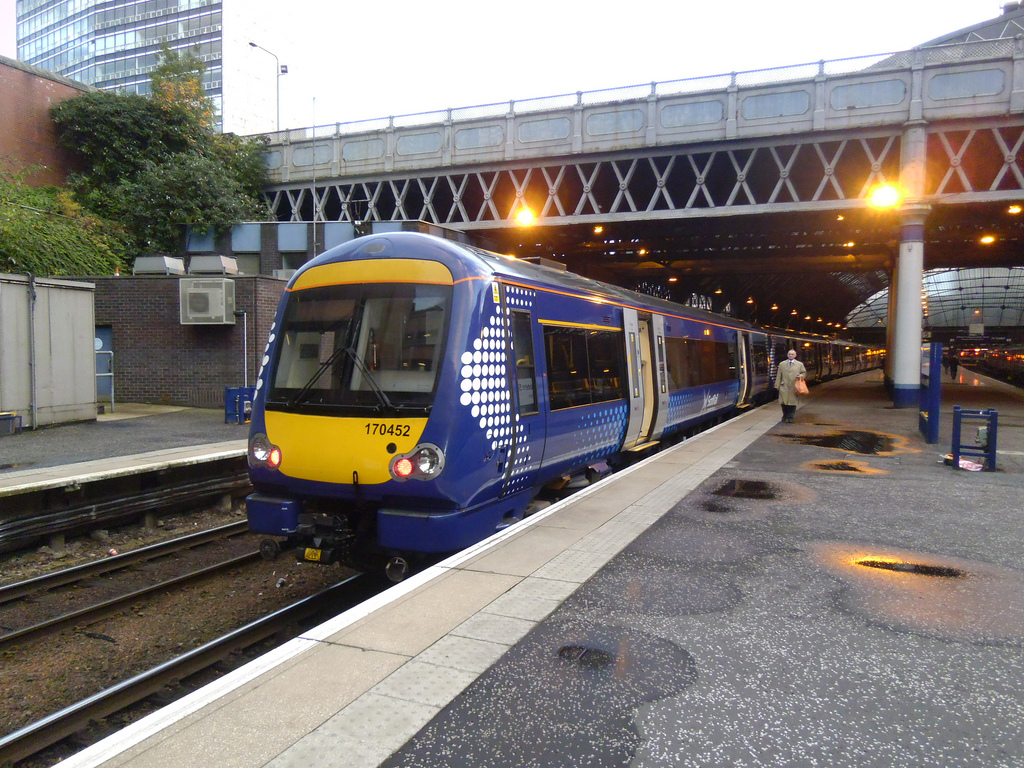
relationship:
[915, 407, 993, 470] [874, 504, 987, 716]
bars on sidewalk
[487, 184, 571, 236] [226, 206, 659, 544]
light above train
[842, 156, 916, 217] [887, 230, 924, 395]
light above post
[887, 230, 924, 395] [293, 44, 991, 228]
post on bridge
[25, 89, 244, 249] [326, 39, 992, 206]
bushes by bridge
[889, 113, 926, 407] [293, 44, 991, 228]
post holding up bridge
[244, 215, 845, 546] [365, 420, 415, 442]
train has numbers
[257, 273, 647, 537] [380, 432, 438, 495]
train has headlight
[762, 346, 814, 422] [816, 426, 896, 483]
person walking by puddle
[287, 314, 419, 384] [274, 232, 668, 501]
windshield of train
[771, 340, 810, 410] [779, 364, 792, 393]
man in coat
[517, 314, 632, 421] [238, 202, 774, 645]
window of train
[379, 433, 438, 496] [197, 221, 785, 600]
headlight of train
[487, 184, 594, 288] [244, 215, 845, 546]
light to left of train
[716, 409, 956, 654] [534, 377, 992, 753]
puddles on asphalt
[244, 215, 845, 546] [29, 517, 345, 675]
train on tracks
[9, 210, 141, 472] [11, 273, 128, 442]
shed with doors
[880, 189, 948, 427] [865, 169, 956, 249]
column with light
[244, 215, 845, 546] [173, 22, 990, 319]
train under overpass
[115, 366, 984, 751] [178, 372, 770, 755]
concrete near stripe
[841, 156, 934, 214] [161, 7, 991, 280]
light on bridge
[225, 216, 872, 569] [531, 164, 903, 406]
train on tunnel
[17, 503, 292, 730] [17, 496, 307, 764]
tracks on ground